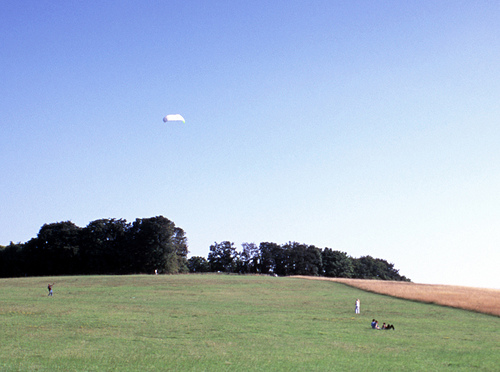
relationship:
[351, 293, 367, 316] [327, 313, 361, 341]
person on grass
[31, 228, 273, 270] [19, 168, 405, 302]
tree in distance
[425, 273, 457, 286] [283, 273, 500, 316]
patch of patch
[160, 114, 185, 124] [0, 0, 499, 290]
parachute in sky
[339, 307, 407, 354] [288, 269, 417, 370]
people on field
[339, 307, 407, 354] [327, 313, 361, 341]
people on grass